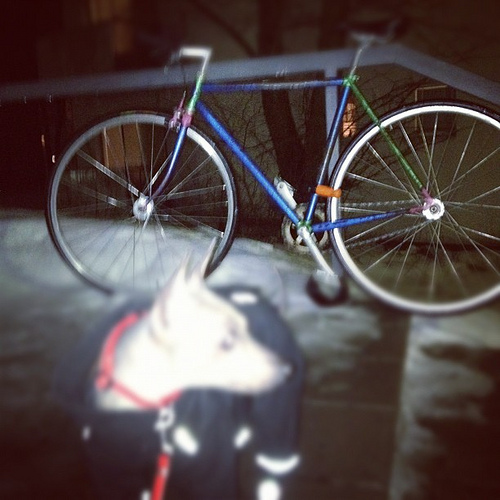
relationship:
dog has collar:
[59, 236, 304, 499] [93, 311, 184, 410]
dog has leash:
[59, 236, 304, 499] [151, 409, 176, 500]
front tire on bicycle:
[44, 106, 239, 297] [44, 13, 500, 319]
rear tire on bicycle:
[324, 98, 500, 317] [44, 13, 500, 319]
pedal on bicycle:
[271, 173, 296, 198] [44, 13, 500, 319]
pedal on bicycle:
[309, 269, 343, 300] [44, 13, 500, 319]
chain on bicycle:
[279, 197, 445, 257] [44, 13, 500, 319]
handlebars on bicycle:
[166, 45, 212, 66] [44, 13, 500, 319]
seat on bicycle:
[338, 14, 409, 47] [44, 13, 500, 319]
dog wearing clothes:
[59, 236, 304, 499] [52, 282, 300, 500]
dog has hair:
[59, 236, 304, 499] [95, 237, 295, 414]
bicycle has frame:
[44, 13, 500, 319] [142, 43, 434, 236]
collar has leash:
[93, 311, 184, 410] [151, 409, 176, 500]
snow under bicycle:
[0, 218, 379, 421] [44, 13, 500, 319]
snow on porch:
[0, 218, 379, 421] [2, 295, 412, 499]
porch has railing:
[2, 295, 412, 499] [1, 41, 500, 282]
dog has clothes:
[59, 236, 304, 499] [52, 282, 300, 500]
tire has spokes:
[44, 106, 239, 297] [55, 123, 228, 283]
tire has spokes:
[324, 98, 500, 317] [338, 112, 499, 303]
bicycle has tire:
[44, 13, 500, 319] [44, 106, 239, 297]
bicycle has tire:
[44, 13, 500, 319] [324, 98, 500, 317]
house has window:
[22, 1, 500, 247] [102, 118, 145, 167]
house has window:
[22, 1, 500, 247] [108, 21, 133, 53]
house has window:
[22, 1, 500, 247] [88, 1, 128, 23]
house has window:
[22, 1, 500, 247] [341, 102, 357, 136]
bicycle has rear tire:
[44, 13, 500, 319] [324, 98, 500, 317]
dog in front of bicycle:
[59, 236, 304, 499] [44, 13, 500, 319]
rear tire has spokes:
[324, 98, 500, 317] [338, 112, 499, 303]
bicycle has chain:
[44, 13, 500, 319] [279, 197, 445, 257]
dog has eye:
[59, 236, 304, 499] [219, 329, 238, 352]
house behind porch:
[22, 1, 500, 247] [2, 295, 412, 499]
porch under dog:
[2, 295, 412, 499] [59, 236, 304, 499]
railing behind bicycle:
[1, 41, 500, 282] [44, 13, 500, 319]